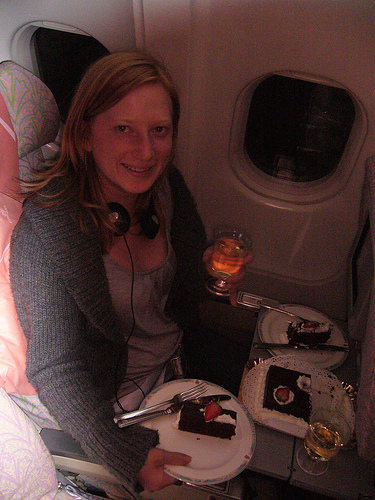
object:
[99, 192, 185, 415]
shirt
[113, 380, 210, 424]
fork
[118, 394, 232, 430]
butter knife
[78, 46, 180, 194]
head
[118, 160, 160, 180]
smile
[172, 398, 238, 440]
cake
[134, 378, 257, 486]
plate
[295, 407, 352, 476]
glass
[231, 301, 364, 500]
tray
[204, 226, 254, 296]
glass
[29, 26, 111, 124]
airplane window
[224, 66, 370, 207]
window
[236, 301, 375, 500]
table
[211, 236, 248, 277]
liquid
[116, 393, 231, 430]
knife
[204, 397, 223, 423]
strawberry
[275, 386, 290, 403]
strawberry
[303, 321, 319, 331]
strawberry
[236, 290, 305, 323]
knife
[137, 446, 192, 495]
hand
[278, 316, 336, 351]
desert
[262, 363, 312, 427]
desert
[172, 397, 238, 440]
desert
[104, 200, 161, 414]
earphones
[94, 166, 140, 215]
neck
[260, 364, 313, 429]
cake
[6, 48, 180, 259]
hair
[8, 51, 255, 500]
person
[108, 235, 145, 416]
wire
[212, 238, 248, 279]
wine